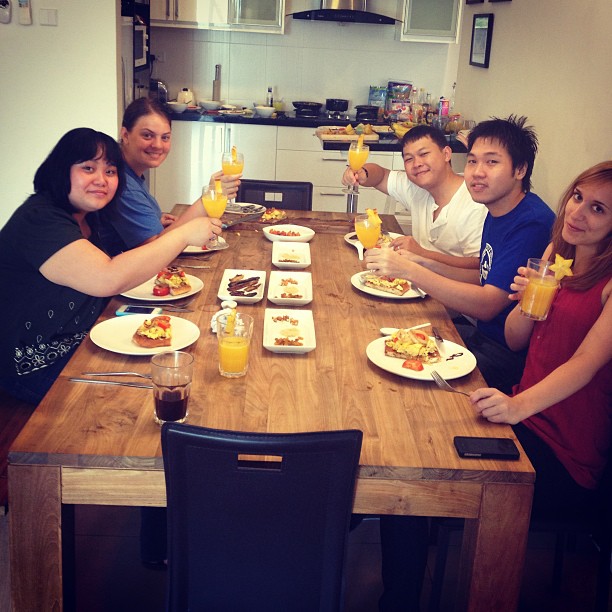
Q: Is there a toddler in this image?
A: No, there are no toddlers.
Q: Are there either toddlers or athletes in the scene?
A: No, there are no toddlers or athletes.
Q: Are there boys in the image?
A: No, there are no boys.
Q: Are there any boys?
A: No, there are no boys.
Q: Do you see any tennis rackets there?
A: No, there are no tennis rackets.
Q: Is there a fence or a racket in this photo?
A: No, there are no rackets or fences.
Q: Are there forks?
A: Yes, there is a fork.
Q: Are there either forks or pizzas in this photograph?
A: Yes, there is a fork.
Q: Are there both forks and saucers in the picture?
A: No, there is a fork but no saucers.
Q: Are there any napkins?
A: No, there are no napkins.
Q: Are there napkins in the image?
A: No, there are no napkins.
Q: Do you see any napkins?
A: No, there are no napkins.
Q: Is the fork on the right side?
A: Yes, the fork is on the right of the image.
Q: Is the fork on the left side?
A: No, the fork is on the right of the image.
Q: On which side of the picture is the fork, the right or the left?
A: The fork is on the right of the image.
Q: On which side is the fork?
A: The fork is on the right of the image.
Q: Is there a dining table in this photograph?
A: Yes, there is a dining table.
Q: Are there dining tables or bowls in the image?
A: Yes, there is a dining table.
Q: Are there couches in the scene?
A: No, there are no couches.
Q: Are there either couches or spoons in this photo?
A: No, there are no couches or spoons.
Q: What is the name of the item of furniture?
A: The piece of furniture is a dining table.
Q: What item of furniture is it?
A: The piece of furniture is a dining table.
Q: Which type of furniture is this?
A: That is a dining table.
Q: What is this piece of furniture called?
A: That is a dining table.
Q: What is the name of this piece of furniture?
A: That is a dining table.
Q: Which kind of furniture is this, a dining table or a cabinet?
A: That is a dining table.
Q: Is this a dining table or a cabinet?
A: This is a dining table.